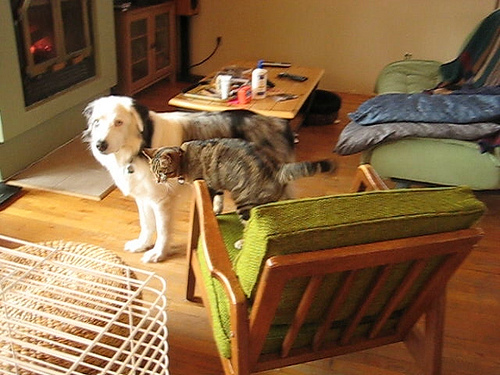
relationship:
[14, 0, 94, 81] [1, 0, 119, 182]
fireplace in wall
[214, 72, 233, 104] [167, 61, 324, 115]
white cup on table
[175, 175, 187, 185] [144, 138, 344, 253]
bell on cat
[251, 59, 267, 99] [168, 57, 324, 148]
bottle on table